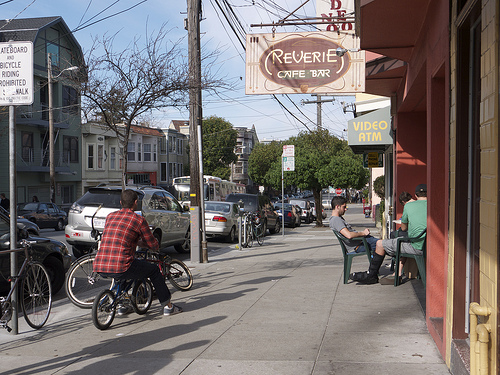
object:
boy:
[91, 188, 182, 316]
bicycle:
[90, 245, 155, 331]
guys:
[328, 183, 429, 286]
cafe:
[244, 1, 452, 363]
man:
[347, 182, 430, 286]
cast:
[345, 251, 384, 284]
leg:
[347, 239, 413, 286]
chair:
[385, 232, 429, 287]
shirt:
[400, 200, 429, 250]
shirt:
[92, 208, 161, 274]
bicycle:
[1, 239, 54, 334]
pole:
[8, 104, 19, 336]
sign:
[243, 27, 367, 95]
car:
[200, 197, 242, 244]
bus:
[170, 172, 245, 207]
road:
[43, 227, 65, 241]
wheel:
[92, 287, 124, 331]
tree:
[49, 49, 232, 189]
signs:
[280, 143, 297, 172]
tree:
[251, 128, 369, 229]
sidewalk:
[1, 203, 446, 375]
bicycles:
[1, 234, 194, 334]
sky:
[81, 2, 356, 142]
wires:
[214, 0, 319, 132]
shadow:
[5, 314, 227, 373]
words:
[352, 118, 390, 142]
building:
[1, 15, 89, 218]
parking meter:
[235, 196, 249, 251]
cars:
[64, 173, 315, 259]